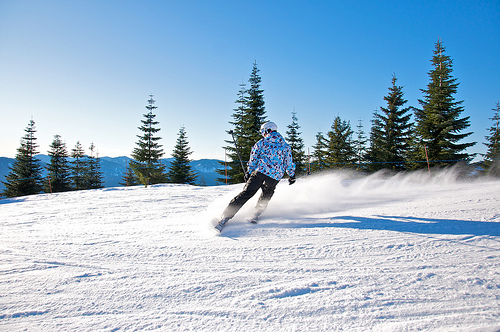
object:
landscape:
[0, 34, 500, 331]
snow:
[0, 177, 498, 331]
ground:
[0, 182, 497, 332]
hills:
[192, 157, 233, 186]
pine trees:
[128, 93, 166, 187]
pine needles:
[430, 114, 438, 121]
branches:
[151, 121, 161, 125]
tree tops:
[148, 93, 156, 99]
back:
[256, 139, 290, 180]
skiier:
[219, 121, 297, 224]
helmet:
[258, 121, 279, 138]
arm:
[286, 146, 298, 178]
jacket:
[246, 132, 296, 181]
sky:
[0, 1, 500, 161]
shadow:
[247, 215, 500, 251]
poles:
[308, 147, 311, 171]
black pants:
[221, 169, 281, 219]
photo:
[0, 0, 499, 330]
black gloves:
[287, 174, 296, 185]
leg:
[220, 171, 264, 223]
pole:
[225, 149, 228, 186]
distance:
[0, 152, 231, 196]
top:
[103, 156, 112, 159]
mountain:
[108, 155, 143, 170]